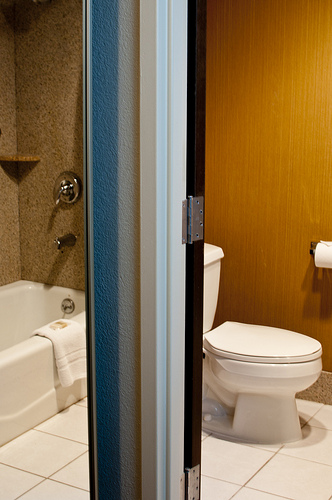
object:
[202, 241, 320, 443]
toilet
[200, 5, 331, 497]
room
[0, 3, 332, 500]
bathroom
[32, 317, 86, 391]
towel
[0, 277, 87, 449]
bathtub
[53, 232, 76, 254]
faucet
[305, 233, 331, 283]
toilet paper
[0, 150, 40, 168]
shelf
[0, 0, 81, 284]
wall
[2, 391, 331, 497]
tile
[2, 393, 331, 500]
floor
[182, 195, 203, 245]
hinge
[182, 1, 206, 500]
door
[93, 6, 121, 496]
line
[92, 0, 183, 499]
wall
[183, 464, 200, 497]
hinge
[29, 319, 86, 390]
bathmat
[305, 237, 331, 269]
toilet paper holder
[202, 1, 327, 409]
wall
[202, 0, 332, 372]
panel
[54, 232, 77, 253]
pipe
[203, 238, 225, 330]
tank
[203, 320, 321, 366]
toilet cover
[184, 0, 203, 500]
toilet door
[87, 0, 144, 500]
door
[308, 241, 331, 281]
roll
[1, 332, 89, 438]
side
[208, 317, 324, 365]
toilet seat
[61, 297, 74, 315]
plug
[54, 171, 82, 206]
cold knob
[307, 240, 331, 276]
holder